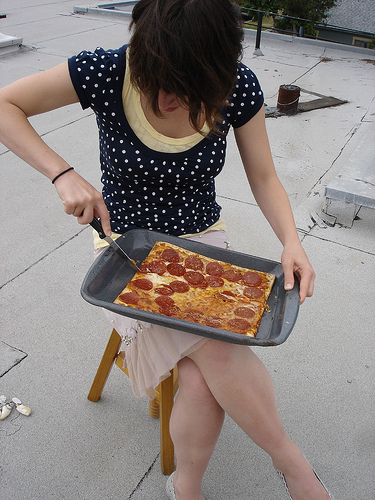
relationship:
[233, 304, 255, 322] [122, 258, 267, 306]
pepperoni on pizza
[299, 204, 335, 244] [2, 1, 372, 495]
road cracks on road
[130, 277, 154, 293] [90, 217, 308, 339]
pepperoni on pizza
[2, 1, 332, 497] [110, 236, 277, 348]
girl cutting pizza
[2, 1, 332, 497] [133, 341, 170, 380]
girl wearing skirt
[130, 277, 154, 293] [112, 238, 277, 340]
pepperoni on pizza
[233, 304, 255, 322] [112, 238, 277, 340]
pepperoni on pizza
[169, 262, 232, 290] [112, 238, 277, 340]
pepperoni on pizza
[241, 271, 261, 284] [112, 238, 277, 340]
pepperoni on pizza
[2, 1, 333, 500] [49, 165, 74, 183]
girl wears bracelet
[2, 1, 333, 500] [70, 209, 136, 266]
girl holds holding knife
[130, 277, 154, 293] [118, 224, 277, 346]
pepperoni on pizza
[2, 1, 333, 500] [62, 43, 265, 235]
girl wears shirt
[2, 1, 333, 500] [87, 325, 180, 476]
girl on chair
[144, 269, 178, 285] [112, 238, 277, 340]
cheese on pizza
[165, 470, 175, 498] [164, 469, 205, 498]
heel of shoe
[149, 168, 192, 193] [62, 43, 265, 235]
polkadots on shirt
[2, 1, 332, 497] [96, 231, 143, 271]
girl holding knife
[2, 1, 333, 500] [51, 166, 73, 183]
girl has bracelet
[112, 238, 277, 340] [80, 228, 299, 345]
pizza in pan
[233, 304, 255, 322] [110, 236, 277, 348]
pepperoni on pizza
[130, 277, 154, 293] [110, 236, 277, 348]
pepperoni on pizza